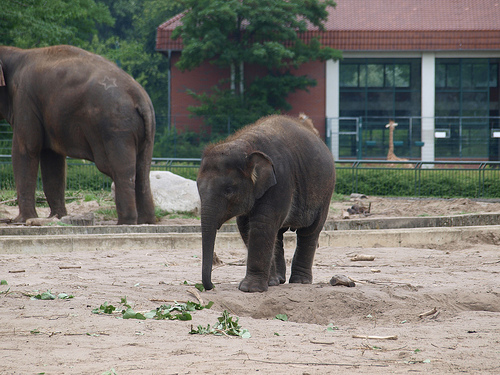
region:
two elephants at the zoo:
[5, 48, 332, 289]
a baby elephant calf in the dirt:
[203, 115, 333, 287]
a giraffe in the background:
[386, 118, 411, 168]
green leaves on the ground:
[30, 293, 243, 337]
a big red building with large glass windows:
[160, 5, 499, 162]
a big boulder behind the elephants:
[122, 174, 202, 209]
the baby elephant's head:
[204, 145, 274, 293]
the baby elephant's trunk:
[200, 215, 218, 290]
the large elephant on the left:
[0, 44, 157, 224]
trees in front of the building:
[182, 0, 329, 152]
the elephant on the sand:
[176, 88, 356, 283]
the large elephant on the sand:
[4, 43, 165, 230]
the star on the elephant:
[90, 70, 121, 97]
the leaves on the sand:
[21, 285, 227, 357]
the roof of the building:
[165, 4, 497, 50]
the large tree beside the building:
[182, 15, 279, 136]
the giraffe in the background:
[366, 121, 418, 163]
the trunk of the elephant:
[195, 220, 220, 298]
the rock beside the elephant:
[146, 163, 196, 210]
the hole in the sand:
[192, 293, 387, 335]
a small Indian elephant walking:
[193, 114, 332, 291]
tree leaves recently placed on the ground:
[89, 287, 241, 340]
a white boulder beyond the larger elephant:
[146, 171, 201, 211]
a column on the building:
[418, 54, 437, 165]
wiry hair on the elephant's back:
[218, 110, 283, 145]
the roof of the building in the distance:
[154, 0, 498, 52]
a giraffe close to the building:
[384, 119, 414, 159]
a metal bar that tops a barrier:
[333, 157, 498, 167]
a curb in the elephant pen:
[1, 223, 498, 250]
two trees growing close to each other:
[175, 1, 340, 151]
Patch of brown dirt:
[27, 338, 43, 361]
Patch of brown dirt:
[68, 336, 123, 368]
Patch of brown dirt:
[153, 339, 167, 351]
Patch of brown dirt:
[211, 341, 252, 371]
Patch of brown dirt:
[255, 336, 297, 371]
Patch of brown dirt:
[319, 341, 397, 371]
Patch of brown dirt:
[410, 324, 447, 363]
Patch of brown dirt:
[411, 259, 441, 300]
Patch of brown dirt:
[133, 283, 188, 330]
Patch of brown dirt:
[35, 262, 84, 301]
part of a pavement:
[411, 212, 435, 244]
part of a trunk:
[225, 205, 232, 216]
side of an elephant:
[299, 178, 311, 182]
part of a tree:
[259, 55, 267, 68]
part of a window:
[407, 115, 412, 130]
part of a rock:
[333, 273, 338, 283]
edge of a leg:
[261, 219, 265, 229]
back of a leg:
[111, 170, 137, 202]